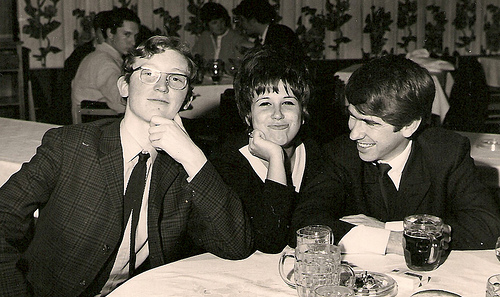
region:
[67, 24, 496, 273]
three people sitting at a table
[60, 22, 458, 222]
three people smiling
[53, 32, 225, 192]
a man with glasses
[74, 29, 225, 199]
a man with glasses smiling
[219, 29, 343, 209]
a women with short hair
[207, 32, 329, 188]
a women with short hair smiling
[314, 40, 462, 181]
a man smiling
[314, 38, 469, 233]
a man looking to the side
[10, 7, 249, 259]
a man in a striped suit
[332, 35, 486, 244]
a man in a black suit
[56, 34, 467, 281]
three people sitting at table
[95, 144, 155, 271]
tie on man's chest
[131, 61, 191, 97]
glasses on man's face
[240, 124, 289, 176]
chin in woman's hand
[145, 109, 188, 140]
fingers on man's chin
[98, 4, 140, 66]
man watching from background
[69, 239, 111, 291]
buttons on man's jacket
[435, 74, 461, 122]
tablecloth on table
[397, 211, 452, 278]
drinking glass on table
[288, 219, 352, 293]
glassware on table top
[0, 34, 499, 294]
three people at a table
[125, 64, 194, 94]
glasses on a man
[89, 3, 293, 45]
people sitting in the background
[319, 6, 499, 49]
floral curtains in the background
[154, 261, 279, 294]
white tablecloth on the table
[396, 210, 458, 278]
glass beverage on table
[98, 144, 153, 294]
tie on a man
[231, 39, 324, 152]
face of a woman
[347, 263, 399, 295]
glass ashtray on a table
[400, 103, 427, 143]
left ear of a man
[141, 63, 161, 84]
the eye of a person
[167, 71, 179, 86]
the eye of a person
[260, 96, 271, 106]
the eye of a person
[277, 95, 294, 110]
the eye of a person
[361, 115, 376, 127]
the eye of a person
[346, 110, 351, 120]
the eye of a person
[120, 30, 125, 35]
the eye of a person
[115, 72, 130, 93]
the ear of a person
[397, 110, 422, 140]
the ear of a person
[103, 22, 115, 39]
the ear of a person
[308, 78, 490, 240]
man in suit smiling at girl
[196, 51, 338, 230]
girl smiling at camera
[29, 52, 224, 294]
man in suit and glasses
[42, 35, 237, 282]
man has tie and is smiling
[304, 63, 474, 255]
man has suit and tie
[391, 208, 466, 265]
drinks on table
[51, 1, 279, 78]
group talking in background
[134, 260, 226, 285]
white table cloth on table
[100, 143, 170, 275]
white shirt under man's suit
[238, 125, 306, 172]
ring on womans finger